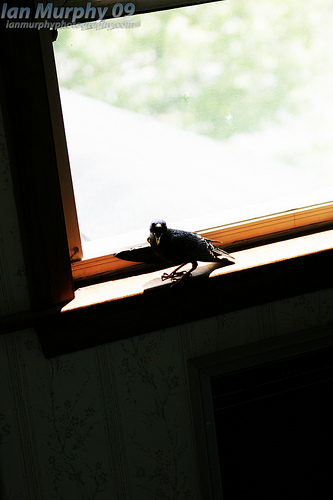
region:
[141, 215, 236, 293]
bird sitting on window sill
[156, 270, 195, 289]
birds two feet on sill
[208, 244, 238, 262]
tail feathers on bird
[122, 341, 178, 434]
flower print on wallpaper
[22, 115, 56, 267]
wood frame around window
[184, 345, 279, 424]
metal vent under window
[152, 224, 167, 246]
yellow beak on bird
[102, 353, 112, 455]
vertical lines on wallpaper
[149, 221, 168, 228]
eyes on bird's head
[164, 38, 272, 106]
vegetation outside of window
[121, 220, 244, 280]
black bird on window sill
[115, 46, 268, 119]
clouds in the sky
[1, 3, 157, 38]
wording on top of window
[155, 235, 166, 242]
beak on black bird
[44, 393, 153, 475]
wall with flowered decoration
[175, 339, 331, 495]
a large square object on wall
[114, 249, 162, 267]
one of the bird's wings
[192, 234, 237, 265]
back portion of black bird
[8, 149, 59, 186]
framed work on side of window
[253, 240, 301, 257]
part of window sill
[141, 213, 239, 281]
Black bird in front of window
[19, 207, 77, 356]
wooden window frame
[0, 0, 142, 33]
Ian Murphy label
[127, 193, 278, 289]
black bird on windowsill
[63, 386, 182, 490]
Flower print wallpaper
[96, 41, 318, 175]
view of outside through window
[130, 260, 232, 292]
Shadow of black bird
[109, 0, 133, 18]
Number 09 in blue text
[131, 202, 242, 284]
Blackbird inside the window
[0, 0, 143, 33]
Blue text on upper corner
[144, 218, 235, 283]
small bird on a window sill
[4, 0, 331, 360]
the wooden window from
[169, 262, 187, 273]
right leg of bird on sill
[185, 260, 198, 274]
right leg of bird on sill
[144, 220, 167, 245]
head of bird on sill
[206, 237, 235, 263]
tail feathers of bird on sill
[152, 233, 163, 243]
beak of bird on sill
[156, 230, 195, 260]
body of bird on sill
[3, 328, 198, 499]
flowered wall paper on bottom left of picture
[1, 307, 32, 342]
section of chair rail on left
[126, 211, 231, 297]
bird on a window sill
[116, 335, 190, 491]
floral pattern on wallpaper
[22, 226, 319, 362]
brown window sill made of wood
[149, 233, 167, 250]
yellow beak on a bird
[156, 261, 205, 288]
talons of a bird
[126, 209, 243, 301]
a black bird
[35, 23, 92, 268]
metal frame on window screen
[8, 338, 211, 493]
white wall paper with floral patterns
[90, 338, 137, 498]
tan stripe on wall paper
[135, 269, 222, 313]
shadow of a bird